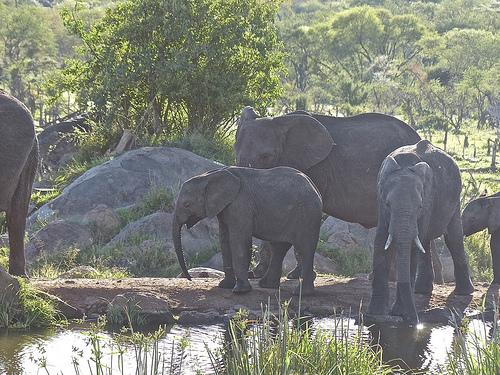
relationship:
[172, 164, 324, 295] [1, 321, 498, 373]
elephant near water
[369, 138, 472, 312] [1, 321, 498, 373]
elephant near water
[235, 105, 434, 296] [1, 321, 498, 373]
elephant near water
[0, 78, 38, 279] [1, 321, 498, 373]
elephant near water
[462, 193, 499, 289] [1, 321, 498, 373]
elephant near water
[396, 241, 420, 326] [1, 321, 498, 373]
trunk in water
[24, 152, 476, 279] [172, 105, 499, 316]
boulders behind elephants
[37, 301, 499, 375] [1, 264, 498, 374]
plants in foreground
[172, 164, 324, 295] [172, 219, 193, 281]
elephant has trunk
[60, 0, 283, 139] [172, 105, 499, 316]
tree behind elephants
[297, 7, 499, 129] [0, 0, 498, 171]
trees in distance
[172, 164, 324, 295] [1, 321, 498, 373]
elephant by water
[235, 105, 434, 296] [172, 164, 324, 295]
adult by baby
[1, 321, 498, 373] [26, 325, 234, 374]
water reflecting sunlight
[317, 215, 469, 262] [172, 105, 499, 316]
rock behind elephants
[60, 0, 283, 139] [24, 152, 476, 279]
tree behind rocks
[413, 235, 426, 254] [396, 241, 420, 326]
husk beside trunk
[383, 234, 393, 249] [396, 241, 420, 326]
husk beside trunk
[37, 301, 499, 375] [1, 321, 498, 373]
weeds from water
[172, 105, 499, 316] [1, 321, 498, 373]
elephants near water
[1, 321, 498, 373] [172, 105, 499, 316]
water for elephants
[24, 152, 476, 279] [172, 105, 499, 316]
rock behind elephants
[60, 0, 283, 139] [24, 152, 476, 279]
tree behind rock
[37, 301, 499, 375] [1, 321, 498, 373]
grass near water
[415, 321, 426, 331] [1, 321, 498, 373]
sun on water